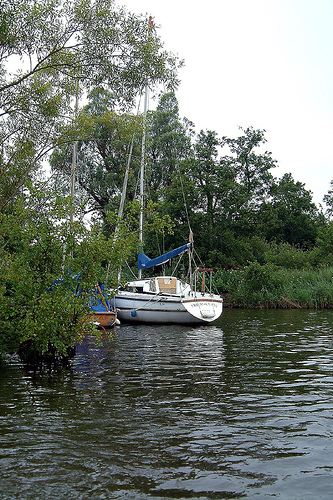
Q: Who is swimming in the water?
A: No one.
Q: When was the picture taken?
A: Daytime.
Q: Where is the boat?
A: On the water.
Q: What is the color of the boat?
A: White.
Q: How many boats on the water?
A: One.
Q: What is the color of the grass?
A: Green.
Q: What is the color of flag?
A: Blue.